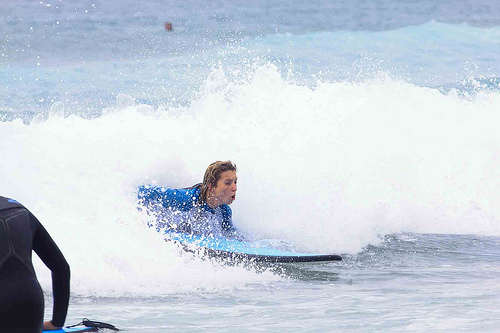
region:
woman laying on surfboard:
[134, 155, 349, 266]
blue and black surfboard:
[165, 227, 357, 259]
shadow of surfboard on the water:
[269, 255, 339, 287]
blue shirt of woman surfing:
[139, 181, 237, 233]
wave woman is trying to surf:
[2, 33, 499, 293]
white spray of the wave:
[2, 71, 497, 272]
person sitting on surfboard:
[3, 195, 96, 332]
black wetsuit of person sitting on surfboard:
[4, 194, 76, 332]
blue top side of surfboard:
[174, 226, 341, 258]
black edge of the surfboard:
[195, 244, 342, 267]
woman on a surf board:
[126, 168, 360, 276]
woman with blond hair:
[192, 153, 251, 210]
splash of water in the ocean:
[216, 53, 446, 229]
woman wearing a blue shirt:
[133, 177, 240, 246]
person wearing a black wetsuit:
[1, 195, 81, 331]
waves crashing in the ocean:
[253, 99, 480, 208]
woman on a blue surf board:
[147, 163, 349, 269]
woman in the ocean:
[126, 180, 252, 235]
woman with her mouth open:
[222, 190, 243, 205]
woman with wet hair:
[188, 158, 255, 205]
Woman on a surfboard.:
[133, 151, 340, 273]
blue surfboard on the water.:
[161, 220, 346, 264]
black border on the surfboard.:
[171, 233, 343, 270]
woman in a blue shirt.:
[130, 157, 242, 243]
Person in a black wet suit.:
[0, 187, 75, 330]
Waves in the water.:
[0, 52, 495, 288]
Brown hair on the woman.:
[190, 155, 235, 210]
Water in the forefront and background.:
[0, 1, 495, 328]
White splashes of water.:
[197, 34, 284, 91]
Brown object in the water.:
[161, 16, 176, 29]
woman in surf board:
[148, 138, 349, 268]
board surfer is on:
[179, 228, 358, 273]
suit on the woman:
[133, 174, 233, 226]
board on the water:
[33, 296, 107, 329]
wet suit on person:
[1, 191, 64, 321]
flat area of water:
[101, 282, 457, 322]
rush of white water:
[258, 81, 473, 214]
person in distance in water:
[157, 15, 179, 34]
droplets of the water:
[16, 13, 47, 53]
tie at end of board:
[81, 312, 118, 332]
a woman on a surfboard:
[127, 153, 351, 265]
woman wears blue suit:
[130, 154, 250, 244]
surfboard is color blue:
[172, 228, 349, 275]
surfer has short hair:
[174, 145, 253, 226]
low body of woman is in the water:
[69, 143, 258, 250]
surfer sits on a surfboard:
[3, 193, 118, 331]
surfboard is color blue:
[41, 318, 97, 329]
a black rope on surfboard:
[62, 312, 128, 329]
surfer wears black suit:
[0, 193, 81, 330]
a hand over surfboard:
[44, 306, 101, 331]